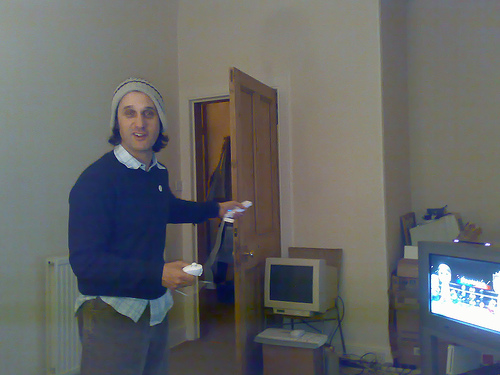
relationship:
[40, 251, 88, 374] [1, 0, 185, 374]
radiator on wall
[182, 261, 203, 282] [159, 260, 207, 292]
wii joystick in hand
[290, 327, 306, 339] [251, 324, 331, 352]
mouse on keyboard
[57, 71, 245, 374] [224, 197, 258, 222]
man holding game controller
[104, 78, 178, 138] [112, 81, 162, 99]
hat has stripe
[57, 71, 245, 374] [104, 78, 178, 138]
man wearing hat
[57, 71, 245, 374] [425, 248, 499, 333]
man playing game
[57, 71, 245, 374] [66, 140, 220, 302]
man wearing shirt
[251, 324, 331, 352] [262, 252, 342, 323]
keyboard in front of monitor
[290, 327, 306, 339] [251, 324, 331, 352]
mouse on top of keyboard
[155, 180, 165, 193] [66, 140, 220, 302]
emblem on shirt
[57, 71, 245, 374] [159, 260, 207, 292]
man has hand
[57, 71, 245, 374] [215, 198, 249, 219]
man has left hand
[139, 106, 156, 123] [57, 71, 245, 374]
left eye of man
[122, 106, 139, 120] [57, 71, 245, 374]
right eye of man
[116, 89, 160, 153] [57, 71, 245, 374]
face of man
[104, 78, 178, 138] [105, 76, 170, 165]
hat on head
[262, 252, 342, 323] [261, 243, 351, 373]
monitor on chair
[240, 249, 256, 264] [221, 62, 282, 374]
doorknob on door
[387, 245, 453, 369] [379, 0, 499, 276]
boxes against wall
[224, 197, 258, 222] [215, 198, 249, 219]
game controller in left hand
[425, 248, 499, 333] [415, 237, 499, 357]
game on television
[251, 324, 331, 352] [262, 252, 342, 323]
keyboard near monitor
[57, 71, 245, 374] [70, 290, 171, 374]
man wearing pants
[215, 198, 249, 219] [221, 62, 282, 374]
left hand by door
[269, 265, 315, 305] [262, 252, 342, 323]
screen on monitor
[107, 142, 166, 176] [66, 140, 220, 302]
shirt collar under shirt